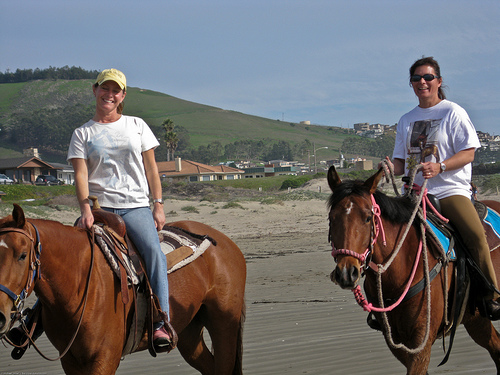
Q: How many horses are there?
A: Two.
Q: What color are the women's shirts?
A: White.